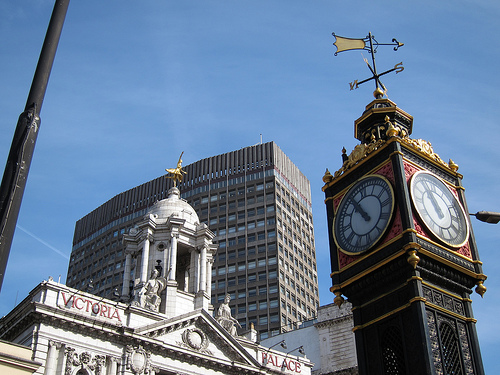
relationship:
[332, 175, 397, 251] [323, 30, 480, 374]
clock in clock tower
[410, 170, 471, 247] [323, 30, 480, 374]
clock in clock tower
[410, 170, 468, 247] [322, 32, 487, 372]
clock in tower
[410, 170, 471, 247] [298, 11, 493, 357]
clock in tower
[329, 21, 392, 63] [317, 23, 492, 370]
yellow vane on clock tower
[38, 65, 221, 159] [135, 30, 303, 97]
clouds against sky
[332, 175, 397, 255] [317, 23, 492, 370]
clock on clock tower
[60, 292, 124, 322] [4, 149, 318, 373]
lettering on building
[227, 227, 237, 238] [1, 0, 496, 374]
window reflecting sky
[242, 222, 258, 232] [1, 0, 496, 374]
window reflecting sky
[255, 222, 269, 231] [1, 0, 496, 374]
window reflecting sky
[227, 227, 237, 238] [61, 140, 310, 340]
window in building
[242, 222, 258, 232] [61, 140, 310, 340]
window in building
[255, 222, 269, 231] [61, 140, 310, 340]
window in building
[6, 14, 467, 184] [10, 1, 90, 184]
sky behind pole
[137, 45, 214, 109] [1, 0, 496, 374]
clouds in sky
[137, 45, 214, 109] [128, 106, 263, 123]
clouds in sky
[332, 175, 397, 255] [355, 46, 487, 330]
clock on a tower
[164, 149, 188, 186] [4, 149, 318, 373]
scultpure on topa building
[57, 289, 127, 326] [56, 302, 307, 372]
lettering on building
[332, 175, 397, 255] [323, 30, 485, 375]
clock on clock tower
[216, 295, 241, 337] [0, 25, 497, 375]
statue on building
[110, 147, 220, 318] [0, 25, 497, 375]
structure on building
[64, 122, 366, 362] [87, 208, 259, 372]
building close to victoria palace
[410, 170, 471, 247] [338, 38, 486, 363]
clock on top of tower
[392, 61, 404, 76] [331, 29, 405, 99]
s sign of spinning piece